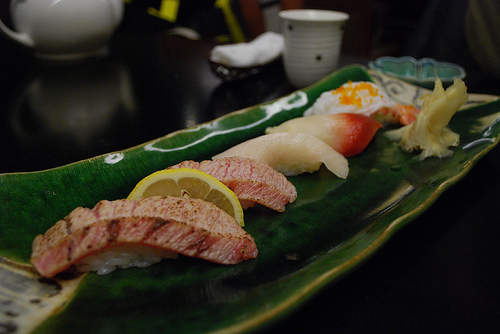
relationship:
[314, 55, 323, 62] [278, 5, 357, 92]
dot on cup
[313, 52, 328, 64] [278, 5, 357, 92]
circle on cup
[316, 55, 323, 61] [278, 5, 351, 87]
circle on cup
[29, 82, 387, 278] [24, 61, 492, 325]
food on plate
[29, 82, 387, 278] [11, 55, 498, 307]
food on plate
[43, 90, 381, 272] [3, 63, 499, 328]
food on dish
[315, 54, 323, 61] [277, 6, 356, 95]
hole in glass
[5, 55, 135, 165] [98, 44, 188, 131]
reflection on table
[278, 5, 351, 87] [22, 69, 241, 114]
cup on table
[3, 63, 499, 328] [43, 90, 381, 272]
dish holding food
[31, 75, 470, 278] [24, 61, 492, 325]
sushi on plate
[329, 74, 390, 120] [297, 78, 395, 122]
topping on creme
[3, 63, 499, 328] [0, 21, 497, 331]
dish on table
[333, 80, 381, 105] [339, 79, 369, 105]
condiment with cheese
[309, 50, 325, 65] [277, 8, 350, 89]
hole in glass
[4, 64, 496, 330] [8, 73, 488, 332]
sushi on plate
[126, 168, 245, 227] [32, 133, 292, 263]
lemon between sushi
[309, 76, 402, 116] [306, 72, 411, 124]
sprinkle on condiment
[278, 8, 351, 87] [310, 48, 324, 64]
cup has dot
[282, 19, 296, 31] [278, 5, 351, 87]
dot on cup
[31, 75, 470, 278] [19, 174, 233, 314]
sushi on plate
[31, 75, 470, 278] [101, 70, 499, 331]
sushi on plate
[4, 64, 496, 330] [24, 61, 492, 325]
sushi on plate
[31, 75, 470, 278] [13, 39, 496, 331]
sushi on plate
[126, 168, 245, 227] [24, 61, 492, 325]
lemon on plate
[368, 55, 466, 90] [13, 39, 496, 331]
bowl on plate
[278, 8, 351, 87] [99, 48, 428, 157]
cup on table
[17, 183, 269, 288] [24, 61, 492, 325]
protein on plate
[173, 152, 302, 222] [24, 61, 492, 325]
protein on plate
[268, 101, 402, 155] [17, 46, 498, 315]
protein on prate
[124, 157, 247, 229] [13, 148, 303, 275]
lemon between protein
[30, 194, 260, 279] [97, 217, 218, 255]
beef has marks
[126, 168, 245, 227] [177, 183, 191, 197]
lemon has seed